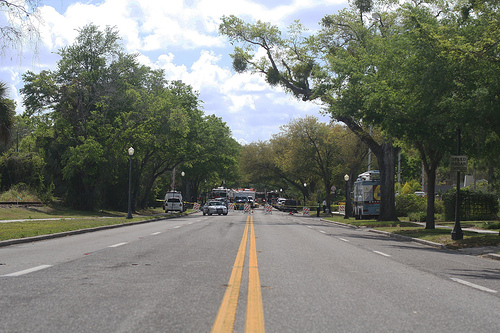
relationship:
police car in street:
[211, 199, 228, 220] [197, 221, 230, 247]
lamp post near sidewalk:
[339, 169, 355, 217] [412, 218, 427, 229]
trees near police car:
[186, 105, 234, 188] [211, 199, 228, 220]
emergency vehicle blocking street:
[236, 184, 256, 209] [197, 221, 230, 247]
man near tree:
[322, 194, 330, 213] [327, 175, 335, 206]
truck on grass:
[351, 168, 382, 219] [368, 219, 383, 234]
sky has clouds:
[184, 31, 219, 67] [163, 19, 190, 43]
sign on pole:
[451, 152, 470, 174] [451, 179, 470, 238]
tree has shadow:
[417, 174, 440, 226] [337, 226, 427, 251]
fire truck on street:
[215, 183, 256, 198] [197, 221, 230, 247]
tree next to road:
[327, 175, 335, 206] [268, 221, 289, 241]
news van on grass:
[351, 168, 382, 219] [368, 219, 383, 234]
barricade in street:
[260, 204, 278, 220] [197, 221, 230, 247]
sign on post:
[451, 152, 468, 172] [456, 175, 463, 236]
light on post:
[127, 146, 137, 155] [127, 161, 133, 211]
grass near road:
[368, 219, 383, 234] [268, 221, 289, 241]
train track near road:
[5, 197, 43, 211] [268, 221, 289, 241]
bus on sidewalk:
[351, 168, 382, 219] [412, 218, 427, 229]